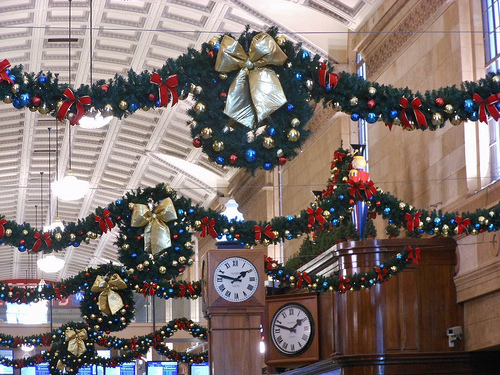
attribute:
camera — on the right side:
[438, 318, 468, 354]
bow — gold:
[213, 31, 288, 131]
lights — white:
[29, 99, 116, 276]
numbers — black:
[213, 254, 252, 298]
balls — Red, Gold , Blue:
[255, 49, 375, 124]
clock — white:
[263, 294, 321, 363]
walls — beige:
[365, 55, 470, 206]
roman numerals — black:
[287, 304, 297, 318]